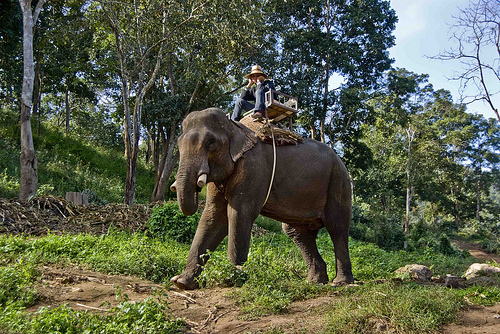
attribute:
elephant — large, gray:
[146, 90, 402, 295]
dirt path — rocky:
[8, 228, 499, 333]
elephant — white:
[156, 99, 359, 286]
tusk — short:
[164, 172, 209, 191]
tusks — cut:
[167, 173, 209, 190]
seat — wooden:
[241, 91, 300, 133]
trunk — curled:
[174, 147, 210, 216]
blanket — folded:
[239, 113, 306, 153]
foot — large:
[162, 270, 202, 290]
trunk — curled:
[172, 157, 197, 202]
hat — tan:
[246, 66, 262, 76]